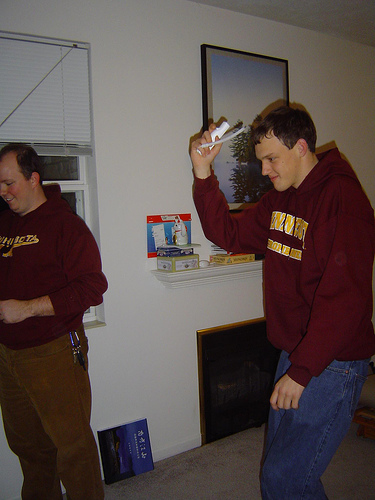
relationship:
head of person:
[246, 105, 319, 198] [181, 95, 373, 500]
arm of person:
[189, 127, 272, 261] [181, 95, 373, 500]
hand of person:
[185, 123, 228, 173] [181, 95, 373, 500]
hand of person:
[266, 373, 310, 416] [181, 95, 373, 500]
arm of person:
[284, 182, 373, 391] [181, 95, 373, 500]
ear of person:
[294, 133, 309, 159] [181, 95, 373, 500]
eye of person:
[265, 155, 281, 165] [181, 95, 373, 500]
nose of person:
[259, 160, 276, 179] [181, 95, 373, 500]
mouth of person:
[265, 172, 277, 182] [181, 95, 373, 500]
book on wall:
[96, 413, 155, 486] [2, 2, 372, 500]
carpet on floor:
[9, 373, 373, 499] [24, 370, 374, 500]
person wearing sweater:
[181, 95, 373, 500] [187, 144, 374, 392]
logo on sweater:
[261, 210, 310, 266] [187, 144, 374, 392]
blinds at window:
[1, 35, 96, 154] [1, 28, 111, 334]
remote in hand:
[197, 119, 246, 162] [185, 123, 228, 173]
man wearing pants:
[1, 136, 118, 500] [1, 324, 109, 500]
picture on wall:
[198, 40, 297, 216] [2, 2, 372, 500]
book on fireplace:
[206, 251, 258, 267] [184, 306, 297, 452]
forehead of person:
[248, 131, 279, 158] [181, 95, 373, 500]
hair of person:
[248, 101, 319, 156] [181, 95, 373, 500]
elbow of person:
[219, 234, 240, 255] [181, 95, 373, 500]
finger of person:
[207, 120, 219, 134] [181, 95, 373, 500]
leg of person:
[259, 375, 365, 499] [181, 95, 373, 500]